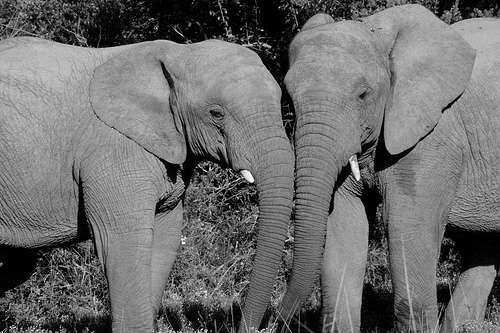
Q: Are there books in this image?
A: No, there are no books.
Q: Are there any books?
A: No, there are no books.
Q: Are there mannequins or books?
A: No, there are no books or mannequins.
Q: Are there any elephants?
A: Yes, there is an elephant.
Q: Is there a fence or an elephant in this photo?
A: Yes, there is an elephant.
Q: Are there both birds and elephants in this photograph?
A: No, there is an elephant but no birds.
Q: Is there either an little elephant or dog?
A: Yes, there is a little elephant.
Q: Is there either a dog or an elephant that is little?
A: Yes, the elephant is little.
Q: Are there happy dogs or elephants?
A: Yes, there is a happy elephant.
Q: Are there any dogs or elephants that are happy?
A: Yes, the elephant is happy.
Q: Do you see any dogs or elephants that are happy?
A: Yes, the elephant is happy.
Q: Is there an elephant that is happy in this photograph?
A: Yes, there is a happy elephant.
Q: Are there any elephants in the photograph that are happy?
A: Yes, there is an elephant that is happy.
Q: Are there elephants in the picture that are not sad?
A: Yes, there is a happy elephant.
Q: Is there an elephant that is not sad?
A: Yes, there is a happy elephant.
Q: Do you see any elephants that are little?
A: Yes, there is a little elephant.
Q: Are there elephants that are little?
A: Yes, there is an elephant that is little.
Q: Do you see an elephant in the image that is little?
A: Yes, there is an elephant that is little.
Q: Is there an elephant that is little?
A: Yes, there is an elephant that is little.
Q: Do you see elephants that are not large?
A: Yes, there is a little elephant.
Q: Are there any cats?
A: No, there are no cats.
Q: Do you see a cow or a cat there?
A: No, there are no cats or cows.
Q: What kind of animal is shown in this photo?
A: The animal is an elephant.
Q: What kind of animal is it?
A: The animal is an elephant.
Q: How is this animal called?
A: This is an elephant.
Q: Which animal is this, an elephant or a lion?
A: This is an elephant.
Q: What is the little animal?
A: The animal is an elephant.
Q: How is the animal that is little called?
A: The animal is an elephant.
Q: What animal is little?
A: The animal is an elephant.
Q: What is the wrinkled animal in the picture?
A: The animal is an elephant.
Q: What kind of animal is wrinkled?
A: The animal is an elephant.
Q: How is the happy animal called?
A: The animal is an elephant.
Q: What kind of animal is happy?
A: The animal is an elephant.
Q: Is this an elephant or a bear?
A: This is an elephant.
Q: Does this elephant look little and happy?
A: Yes, the elephant is little and happy.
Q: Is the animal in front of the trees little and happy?
A: Yes, the elephant is little and happy.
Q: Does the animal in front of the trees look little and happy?
A: Yes, the elephant is little and happy.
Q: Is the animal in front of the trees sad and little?
A: No, the elephant is little but happy.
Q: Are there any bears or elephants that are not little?
A: No, there is an elephant but it is little.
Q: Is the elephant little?
A: Yes, the elephant is little.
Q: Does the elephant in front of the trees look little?
A: Yes, the elephant is little.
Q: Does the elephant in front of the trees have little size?
A: Yes, the elephant is little.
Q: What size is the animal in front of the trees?
A: The elephant is little.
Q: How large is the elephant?
A: The elephant is little.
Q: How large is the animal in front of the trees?
A: The elephant is little.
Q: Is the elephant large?
A: No, the elephant is little.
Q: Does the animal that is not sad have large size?
A: No, the elephant is little.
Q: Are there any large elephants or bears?
A: No, there is an elephant but it is little.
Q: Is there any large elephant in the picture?
A: No, there is an elephant but it is little.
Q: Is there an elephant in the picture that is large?
A: No, there is an elephant but it is little.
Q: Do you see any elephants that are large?
A: No, there is an elephant but it is little.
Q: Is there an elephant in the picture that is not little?
A: No, there is an elephant but it is little.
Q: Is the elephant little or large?
A: The elephant is little.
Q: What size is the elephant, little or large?
A: The elephant is little.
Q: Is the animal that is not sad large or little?
A: The elephant is little.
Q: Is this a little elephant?
A: Yes, this is a little elephant.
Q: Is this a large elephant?
A: No, this is a little elephant.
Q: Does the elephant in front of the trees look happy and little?
A: Yes, the elephant is happy and little.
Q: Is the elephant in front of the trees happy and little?
A: Yes, the elephant is happy and little.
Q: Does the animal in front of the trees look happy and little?
A: Yes, the elephant is happy and little.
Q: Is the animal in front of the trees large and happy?
A: No, the elephant is happy but little.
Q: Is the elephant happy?
A: Yes, the elephant is happy.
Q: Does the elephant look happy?
A: Yes, the elephant is happy.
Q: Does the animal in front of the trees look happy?
A: Yes, the elephant is happy.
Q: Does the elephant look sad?
A: No, the elephant is happy.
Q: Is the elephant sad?
A: No, the elephant is happy.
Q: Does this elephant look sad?
A: No, the elephant is happy.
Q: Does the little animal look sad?
A: No, the elephant is happy.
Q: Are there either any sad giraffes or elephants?
A: No, there is an elephant but it is happy.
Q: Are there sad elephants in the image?
A: No, there is an elephant but it is happy.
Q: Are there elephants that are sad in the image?
A: No, there is an elephant but it is happy.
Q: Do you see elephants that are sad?
A: No, there is an elephant but it is happy.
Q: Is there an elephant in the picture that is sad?
A: No, there is an elephant but it is happy.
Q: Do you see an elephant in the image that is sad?
A: No, there is an elephant but it is happy.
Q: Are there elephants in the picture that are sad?
A: No, there is an elephant but it is happy.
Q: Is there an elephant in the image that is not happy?
A: No, there is an elephant but it is happy.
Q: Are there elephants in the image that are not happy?
A: No, there is an elephant but it is happy.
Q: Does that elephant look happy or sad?
A: The elephant is happy.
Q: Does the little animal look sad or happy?
A: The elephant is happy.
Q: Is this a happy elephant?
A: Yes, this is a happy elephant.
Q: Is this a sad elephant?
A: No, this is a happy elephant.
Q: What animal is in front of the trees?
A: The elephant is in front of the trees.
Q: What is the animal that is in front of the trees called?
A: The animal is an elephant.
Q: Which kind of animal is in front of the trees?
A: The animal is an elephant.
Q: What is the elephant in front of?
A: The elephant is in front of the trees.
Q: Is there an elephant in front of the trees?
A: Yes, there is an elephant in front of the trees.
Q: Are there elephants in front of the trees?
A: Yes, there is an elephant in front of the trees.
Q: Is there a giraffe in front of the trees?
A: No, there is an elephant in front of the trees.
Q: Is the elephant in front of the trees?
A: Yes, the elephant is in front of the trees.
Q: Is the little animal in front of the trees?
A: Yes, the elephant is in front of the trees.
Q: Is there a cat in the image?
A: No, there are no cats.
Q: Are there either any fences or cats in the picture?
A: No, there are no cats or fences.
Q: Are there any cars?
A: No, there are no cars.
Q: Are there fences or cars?
A: No, there are no cars or fences.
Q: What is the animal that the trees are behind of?
A: The animal is an elephant.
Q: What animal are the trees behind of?
A: The trees are behind the elephant.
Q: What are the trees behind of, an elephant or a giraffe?
A: The trees are behind an elephant.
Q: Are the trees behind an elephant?
A: Yes, the trees are behind an elephant.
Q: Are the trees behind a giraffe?
A: No, the trees are behind an elephant.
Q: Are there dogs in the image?
A: No, there are no dogs.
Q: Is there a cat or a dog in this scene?
A: No, there are no dogs or cats.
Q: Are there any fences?
A: No, there are no fences.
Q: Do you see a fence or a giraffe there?
A: No, there are no fences or giraffes.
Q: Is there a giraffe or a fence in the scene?
A: No, there are no fences or giraffes.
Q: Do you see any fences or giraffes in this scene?
A: No, there are no fences or giraffes.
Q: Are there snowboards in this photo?
A: No, there are no snowboards.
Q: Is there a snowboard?
A: No, there are no snowboards.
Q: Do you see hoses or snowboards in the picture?
A: No, there are no snowboards or hoses.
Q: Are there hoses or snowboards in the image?
A: No, there are no snowboards or hoses.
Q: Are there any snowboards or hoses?
A: No, there are no snowboards or hoses.